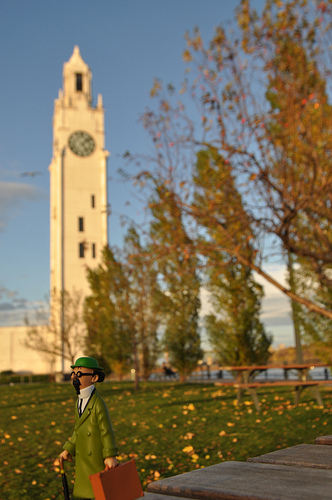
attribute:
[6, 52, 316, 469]
fall — happening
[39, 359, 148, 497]
person — cartoon, toy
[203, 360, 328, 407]
bench — wooden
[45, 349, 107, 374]
hat — green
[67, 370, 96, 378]
glasses — black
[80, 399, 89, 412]
tie — black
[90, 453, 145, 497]
suitcase — brown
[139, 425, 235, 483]
leaves — yellow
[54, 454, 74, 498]
umbrella — black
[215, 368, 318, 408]
table — brown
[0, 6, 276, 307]
sky — clear, white